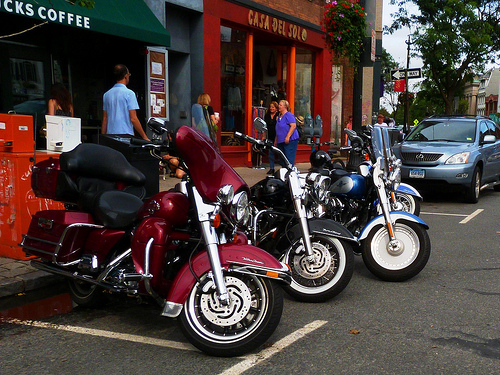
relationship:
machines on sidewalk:
[12, 116, 72, 147] [238, 167, 253, 173]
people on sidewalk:
[79, 89, 299, 135] [238, 167, 253, 173]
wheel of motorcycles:
[177, 261, 254, 336] [91, 206, 377, 253]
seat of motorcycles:
[60, 142, 152, 187] [91, 206, 377, 253]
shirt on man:
[107, 93, 141, 108] [105, 60, 142, 141]